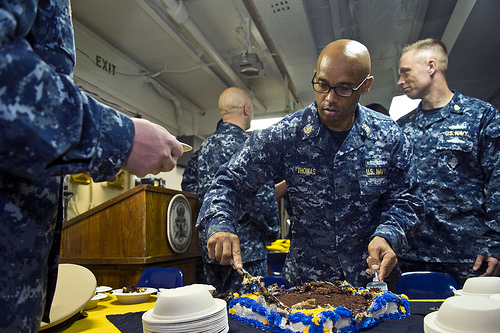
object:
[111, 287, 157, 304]
bowl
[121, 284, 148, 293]
cake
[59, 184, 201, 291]
desk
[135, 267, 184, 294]
chair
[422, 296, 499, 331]
stack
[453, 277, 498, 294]
stack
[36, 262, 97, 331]
white plate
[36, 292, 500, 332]
table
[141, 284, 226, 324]
bowls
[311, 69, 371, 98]
glasses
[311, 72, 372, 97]
frame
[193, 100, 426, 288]
man's uniform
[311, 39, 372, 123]
head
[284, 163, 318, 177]
engraving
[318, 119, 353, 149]
vest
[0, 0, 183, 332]
man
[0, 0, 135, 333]
uniform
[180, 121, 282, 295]
uniform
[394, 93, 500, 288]
uniform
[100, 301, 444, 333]
tablecloth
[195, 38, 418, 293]
man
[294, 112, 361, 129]
floor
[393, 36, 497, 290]
man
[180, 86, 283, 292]
man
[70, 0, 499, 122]
ceiling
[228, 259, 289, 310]
knife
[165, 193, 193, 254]
emblem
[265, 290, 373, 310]
frosting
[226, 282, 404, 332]
cake